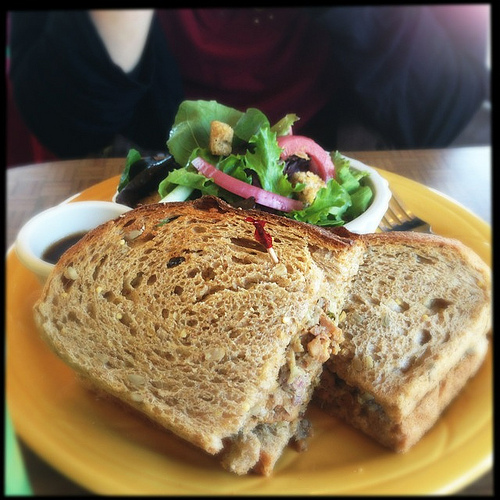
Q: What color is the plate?
A: Yellow.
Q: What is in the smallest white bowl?
A: Salad dressing.